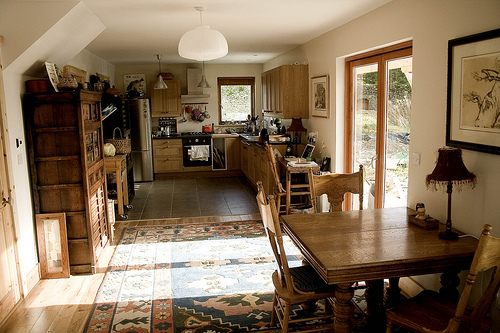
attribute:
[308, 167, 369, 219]
chairs — brown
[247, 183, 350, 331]
chairs — brown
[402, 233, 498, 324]
chairs — brown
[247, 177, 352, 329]
chair — wooden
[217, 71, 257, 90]
framing — wood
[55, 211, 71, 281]
frame — thick, wood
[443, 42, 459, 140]
frame — thick, wood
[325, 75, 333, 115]
frame — thick, wood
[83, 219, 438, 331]
carpet — large, blue, red, white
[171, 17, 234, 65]
light — white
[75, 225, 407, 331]
carpet — large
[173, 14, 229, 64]
lamp — white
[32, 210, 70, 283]
picture — framed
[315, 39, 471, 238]
door — glass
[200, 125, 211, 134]
pot — orange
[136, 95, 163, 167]
refrigerator — silver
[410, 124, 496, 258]
lamp — dark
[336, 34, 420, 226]
patio door — wooden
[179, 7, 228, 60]
light — white and round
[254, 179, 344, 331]
chair — wood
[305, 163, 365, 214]
chair — wood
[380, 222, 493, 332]
chair — wood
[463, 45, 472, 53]
matting — white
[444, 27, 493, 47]
frame — black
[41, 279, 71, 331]
floor — light, brown, wood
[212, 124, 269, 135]
counter — black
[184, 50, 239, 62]
fixtures — silver